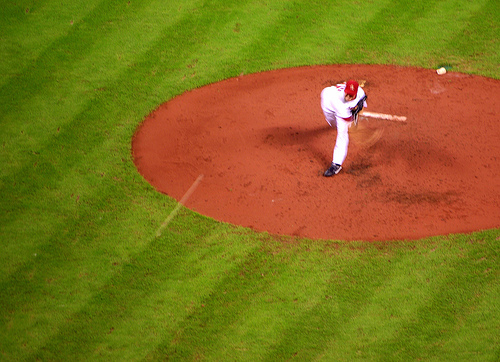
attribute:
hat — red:
[343, 76, 361, 99]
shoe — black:
[321, 162, 344, 177]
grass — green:
[0, 245, 499, 360]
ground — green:
[1, 0, 493, 360]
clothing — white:
[321, 85, 369, 167]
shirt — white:
[320, 81, 366, 123]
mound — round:
[133, 62, 497, 244]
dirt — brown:
[133, 65, 499, 243]